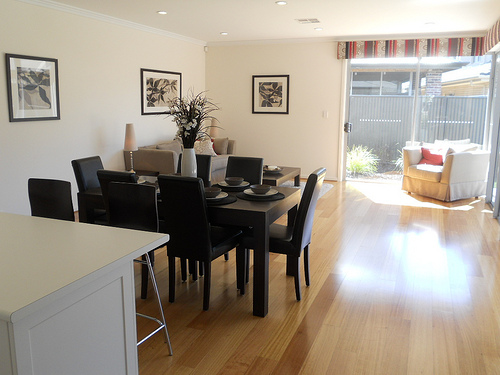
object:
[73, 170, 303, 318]
table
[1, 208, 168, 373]
counter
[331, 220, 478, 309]
light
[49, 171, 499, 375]
floor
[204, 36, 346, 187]
wall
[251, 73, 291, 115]
picture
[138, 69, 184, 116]
picture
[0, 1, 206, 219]
wall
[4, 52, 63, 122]
picture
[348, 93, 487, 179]
fence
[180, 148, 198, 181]
vase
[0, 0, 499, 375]
living space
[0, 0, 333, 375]
dining space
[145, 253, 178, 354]
leg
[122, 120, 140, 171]
lamp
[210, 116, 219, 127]
lamp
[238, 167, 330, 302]
chair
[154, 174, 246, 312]
chair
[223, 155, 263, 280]
chair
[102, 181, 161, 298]
chair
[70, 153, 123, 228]
chair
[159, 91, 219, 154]
flower arrangement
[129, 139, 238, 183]
couch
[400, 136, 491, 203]
chair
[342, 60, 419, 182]
sliding doors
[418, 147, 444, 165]
pillow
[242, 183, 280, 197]
china setting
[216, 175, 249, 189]
china setting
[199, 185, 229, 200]
china setting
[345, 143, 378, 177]
plant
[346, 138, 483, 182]
yard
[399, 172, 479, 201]
corner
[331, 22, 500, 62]
valence